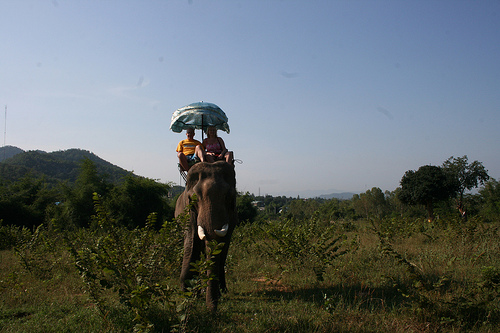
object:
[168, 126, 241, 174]
people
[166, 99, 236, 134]
parasol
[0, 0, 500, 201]
sky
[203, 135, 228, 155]
tank top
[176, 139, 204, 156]
shirt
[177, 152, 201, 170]
shorts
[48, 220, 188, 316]
bushes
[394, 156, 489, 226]
tree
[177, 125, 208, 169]
man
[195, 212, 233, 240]
tusks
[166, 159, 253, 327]
elephant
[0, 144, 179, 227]
hills